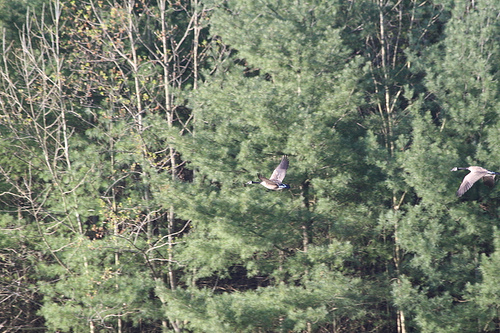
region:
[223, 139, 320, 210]
The bird is flying.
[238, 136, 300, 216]
The bird is soaring.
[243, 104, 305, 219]
The bird is in flight.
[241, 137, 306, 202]
The bird is airborne.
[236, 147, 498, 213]
The birds are facing one another.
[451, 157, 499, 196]
The bird is flying.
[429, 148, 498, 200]
The bird is soaring.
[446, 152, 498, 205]
The bird is in flight.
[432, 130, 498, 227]
The bird is airborne.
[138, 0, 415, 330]
The tree is green.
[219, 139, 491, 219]
two ducks flying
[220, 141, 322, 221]
a duck flying in the air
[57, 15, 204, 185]
a tree with few leaves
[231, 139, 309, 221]
a duck with wings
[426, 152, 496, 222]
a duck flying by trees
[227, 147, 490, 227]
two ducks flying by trees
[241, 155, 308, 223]
a duck with a long neck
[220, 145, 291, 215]
a duck with a black face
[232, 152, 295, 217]
a duck with its wings spread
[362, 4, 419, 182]
a tall tree with no leaves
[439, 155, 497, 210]
flying goose with wings expanded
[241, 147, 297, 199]
leader goose with wings outstretched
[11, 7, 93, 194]
slender brown leafless tree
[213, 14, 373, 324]
large green pine tree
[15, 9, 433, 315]
thick lush evergreen forest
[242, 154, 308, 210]
goose in mid flight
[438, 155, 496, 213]
goose with outstretched neck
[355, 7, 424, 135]
slim leafless tree branches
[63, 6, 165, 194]
yellow leaves on thin hardwood tree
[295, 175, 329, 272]
tall pine tree trunk in shadow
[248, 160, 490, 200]
two ducks in the sky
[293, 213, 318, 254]
a tree trunk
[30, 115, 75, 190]
tree branches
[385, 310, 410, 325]
a tree trunk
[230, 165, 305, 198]
a duck flying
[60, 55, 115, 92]
leaves on the trees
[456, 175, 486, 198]
the ducks wing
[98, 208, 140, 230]
the small leaves on the trees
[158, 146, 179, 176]
a long tree trunk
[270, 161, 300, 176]
the wing of the duck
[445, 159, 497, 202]
ducks flying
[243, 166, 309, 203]
a duck in the sky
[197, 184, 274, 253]
the tree leaves are green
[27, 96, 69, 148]
the tree branches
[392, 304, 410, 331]
tree branches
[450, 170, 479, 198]
a ducks wing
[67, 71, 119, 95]
leaves on the tree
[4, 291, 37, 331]
tree branches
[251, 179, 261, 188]
neck of the duck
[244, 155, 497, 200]
two ducks flying